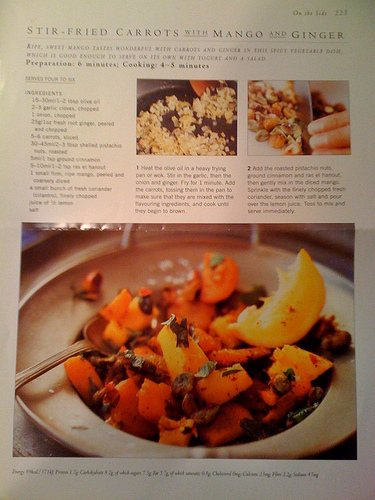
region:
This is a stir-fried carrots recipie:
[14, 14, 196, 42]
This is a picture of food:
[65, 283, 326, 445]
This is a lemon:
[217, 280, 360, 342]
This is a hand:
[298, 95, 355, 179]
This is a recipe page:
[25, 13, 366, 486]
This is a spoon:
[56, 341, 101, 389]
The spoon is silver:
[34, 314, 119, 426]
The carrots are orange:
[79, 288, 234, 413]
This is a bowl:
[39, 262, 371, 431]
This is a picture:
[131, 63, 257, 191]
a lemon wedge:
[226, 248, 325, 347]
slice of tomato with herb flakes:
[203, 250, 239, 301]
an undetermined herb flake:
[194, 360, 217, 376]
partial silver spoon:
[16, 313, 124, 388]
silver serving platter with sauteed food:
[18, 223, 360, 458]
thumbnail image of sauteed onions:
[136, 78, 236, 154]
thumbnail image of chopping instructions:
[248, 80, 350, 153]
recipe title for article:
[23, 25, 346, 38]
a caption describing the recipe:
[10, 467, 321, 478]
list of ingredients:
[23, 90, 124, 213]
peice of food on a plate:
[222, 247, 324, 349]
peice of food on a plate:
[190, 362, 250, 402]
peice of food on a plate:
[263, 345, 332, 386]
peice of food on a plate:
[138, 377, 173, 426]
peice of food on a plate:
[153, 318, 207, 377]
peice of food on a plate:
[191, 251, 241, 305]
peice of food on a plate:
[95, 285, 154, 336]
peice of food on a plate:
[59, 349, 102, 404]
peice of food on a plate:
[68, 266, 110, 308]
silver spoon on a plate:
[11, 312, 116, 412]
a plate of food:
[18, 223, 355, 454]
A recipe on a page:
[13, 21, 355, 485]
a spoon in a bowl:
[31, 305, 155, 396]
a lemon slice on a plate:
[231, 246, 335, 369]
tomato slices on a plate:
[180, 243, 248, 312]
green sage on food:
[190, 355, 223, 391]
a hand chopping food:
[251, 70, 369, 160]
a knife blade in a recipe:
[296, 79, 318, 155]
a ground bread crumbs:
[134, 83, 241, 159]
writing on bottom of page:
[9, 467, 335, 483]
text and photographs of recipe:
[5, 3, 358, 489]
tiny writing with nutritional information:
[9, 461, 321, 476]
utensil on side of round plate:
[16, 271, 142, 406]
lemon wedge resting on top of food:
[77, 245, 339, 448]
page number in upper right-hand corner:
[331, 6, 348, 13]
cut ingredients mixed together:
[68, 252, 329, 442]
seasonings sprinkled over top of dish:
[72, 244, 319, 443]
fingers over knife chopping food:
[241, 71, 352, 155]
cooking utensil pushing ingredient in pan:
[132, 75, 237, 156]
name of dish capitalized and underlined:
[23, 23, 347, 45]